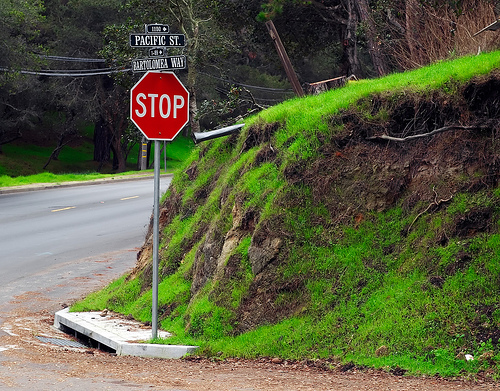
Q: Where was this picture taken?
A: At an intersection.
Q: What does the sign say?
A: Stop.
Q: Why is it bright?
A: It's daylight.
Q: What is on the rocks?
A: Moss.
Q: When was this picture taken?
A: During the day.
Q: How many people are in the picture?
A: None.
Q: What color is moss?
A: Green.